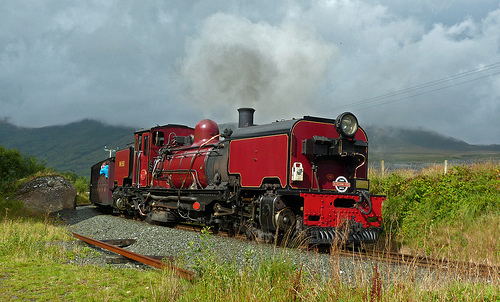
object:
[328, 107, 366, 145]
light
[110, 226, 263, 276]
gravel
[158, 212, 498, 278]
tracks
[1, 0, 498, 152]
sky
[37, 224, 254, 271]
ground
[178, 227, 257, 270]
stack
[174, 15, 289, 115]
smoke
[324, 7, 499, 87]
clouds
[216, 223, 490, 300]
weeds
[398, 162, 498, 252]
grass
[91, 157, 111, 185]
man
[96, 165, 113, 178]
shirt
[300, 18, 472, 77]
white clouds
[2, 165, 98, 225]
boulder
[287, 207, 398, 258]
bumper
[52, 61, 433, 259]
steam engine